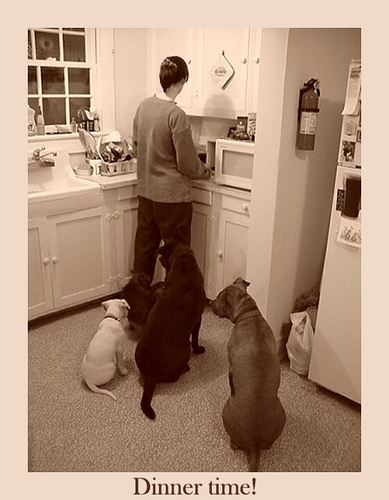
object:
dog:
[134, 237, 204, 420]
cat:
[122, 270, 167, 330]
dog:
[82, 298, 130, 401]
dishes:
[111, 146, 124, 158]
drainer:
[101, 162, 137, 176]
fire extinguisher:
[296, 78, 320, 150]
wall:
[246, 29, 286, 317]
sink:
[28, 173, 100, 200]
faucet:
[33, 146, 57, 166]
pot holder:
[207, 53, 234, 89]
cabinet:
[202, 30, 246, 112]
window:
[27, 28, 91, 134]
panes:
[43, 67, 65, 93]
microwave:
[215, 138, 255, 190]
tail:
[250, 452, 259, 470]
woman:
[131, 56, 201, 287]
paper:
[337, 218, 361, 249]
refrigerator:
[308, 62, 370, 406]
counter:
[27, 175, 252, 322]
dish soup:
[37, 106, 45, 135]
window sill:
[28, 132, 109, 143]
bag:
[286, 312, 313, 375]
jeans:
[134, 197, 193, 283]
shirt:
[133, 95, 205, 203]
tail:
[141, 382, 155, 419]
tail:
[86, 383, 116, 400]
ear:
[234, 277, 250, 286]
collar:
[103, 314, 119, 321]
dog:
[211, 277, 285, 471]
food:
[204, 164, 211, 179]